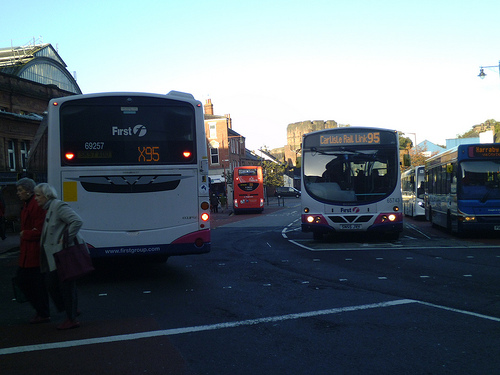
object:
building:
[285, 120, 338, 169]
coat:
[40, 197, 84, 272]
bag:
[52, 227, 98, 278]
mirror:
[403, 154, 411, 166]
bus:
[29, 91, 207, 260]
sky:
[1, 0, 498, 147]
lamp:
[477, 68, 487, 79]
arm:
[60, 207, 83, 237]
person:
[211, 194, 221, 213]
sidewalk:
[209, 209, 282, 228]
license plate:
[341, 225, 362, 230]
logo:
[113, 125, 147, 137]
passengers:
[208, 190, 228, 215]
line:
[0, 298, 497, 355]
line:
[281, 218, 500, 251]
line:
[406, 223, 431, 242]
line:
[377, 276, 386, 279]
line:
[421, 275, 429, 278]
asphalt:
[0, 203, 500, 375]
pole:
[480, 64, 500, 69]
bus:
[301, 126, 404, 240]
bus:
[401, 165, 426, 219]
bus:
[233, 165, 265, 213]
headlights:
[382, 206, 398, 222]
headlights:
[304, 208, 320, 224]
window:
[59, 95, 195, 166]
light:
[65, 153, 75, 161]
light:
[182, 151, 192, 158]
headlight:
[464, 216, 474, 223]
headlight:
[388, 214, 396, 221]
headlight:
[307, 216, 314, 222]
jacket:
[20, 197, 44, 268]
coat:
[17, 194, 50, 318]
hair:
[16, 177, 35, 191]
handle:
[62, 224, 79, 248]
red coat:
[19, 198, 47, 269]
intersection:
[157, 254, 500, 375]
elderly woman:
[15, 176, 49, 322]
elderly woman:
[34, 183, 83, 330]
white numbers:
[85, 141, 103, 149]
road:
[0, 206, 500, 375]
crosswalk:
[0, 250, 500, 375]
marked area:
[211, 234, 483, 344]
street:
[0, 210, 500, 375]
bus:
[425, 143, 500, 234]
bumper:
[301, 222, 403, 232]